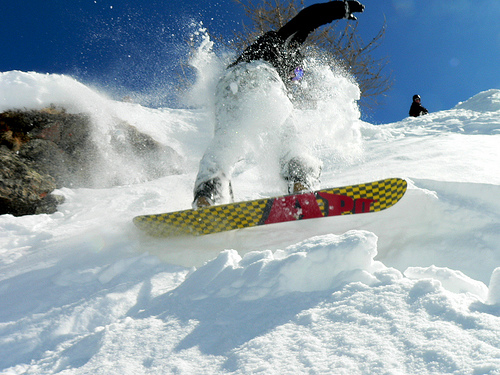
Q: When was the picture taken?
A: Daytime.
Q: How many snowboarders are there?
A: One.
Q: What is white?
A: Snow.